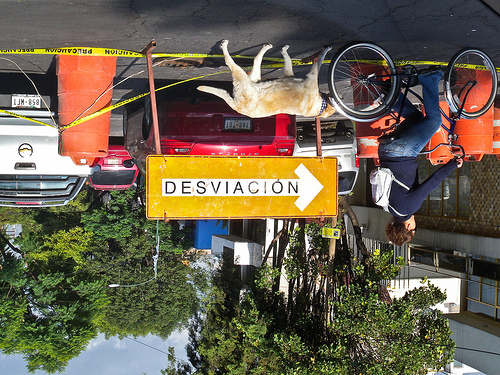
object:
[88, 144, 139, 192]
car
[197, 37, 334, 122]
dog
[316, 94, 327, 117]
collar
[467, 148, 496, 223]
wall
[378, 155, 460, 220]
shirt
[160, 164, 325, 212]
arrow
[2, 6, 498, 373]
picture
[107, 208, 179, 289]
post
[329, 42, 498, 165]
bicycle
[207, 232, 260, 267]
balcony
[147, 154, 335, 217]
sign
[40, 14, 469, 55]
ground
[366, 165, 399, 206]
backpack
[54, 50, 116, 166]
blockade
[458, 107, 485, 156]
ground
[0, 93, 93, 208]
car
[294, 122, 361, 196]
car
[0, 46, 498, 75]
caution tape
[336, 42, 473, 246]
pedestrian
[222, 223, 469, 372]
tree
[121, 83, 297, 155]
sedan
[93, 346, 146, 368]
skies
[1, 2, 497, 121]
road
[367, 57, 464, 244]
man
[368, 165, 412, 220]
backpack